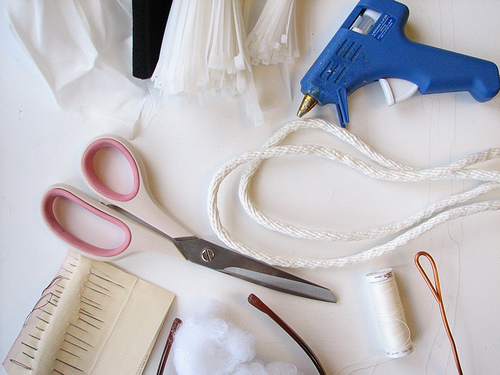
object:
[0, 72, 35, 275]
table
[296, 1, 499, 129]
glue gun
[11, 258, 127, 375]
needles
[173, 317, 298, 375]
cotton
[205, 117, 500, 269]
rope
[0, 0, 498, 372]
craft supples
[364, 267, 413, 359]
spool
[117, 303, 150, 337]
paper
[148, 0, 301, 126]
plastic ties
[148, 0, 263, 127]
bunch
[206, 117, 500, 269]
cord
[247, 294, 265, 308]
edge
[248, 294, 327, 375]
eyeglasses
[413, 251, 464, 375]
wick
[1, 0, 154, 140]
cloth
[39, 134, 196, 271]
pink grips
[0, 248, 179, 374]
package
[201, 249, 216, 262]
screw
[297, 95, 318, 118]
tip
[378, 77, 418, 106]
white trigger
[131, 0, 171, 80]
blades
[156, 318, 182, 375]
frame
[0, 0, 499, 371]
white surface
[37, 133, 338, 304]
objects